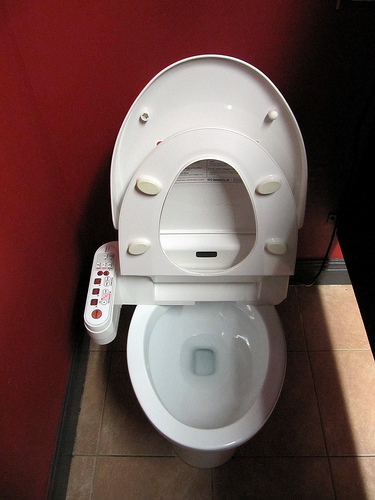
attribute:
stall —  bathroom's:
[1, 8, 366, 490]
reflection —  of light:
[230, 331, 254, 348]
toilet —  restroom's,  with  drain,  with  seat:
[83, 53, 310, 470]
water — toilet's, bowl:
[179, 336, 233, 383]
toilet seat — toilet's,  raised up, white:
[118, 125, 297, 278]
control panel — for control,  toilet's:
[83, 242, 117, 328]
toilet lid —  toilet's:
[109, 54, 309, 270]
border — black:
[47, 336, 89, 500]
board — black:
[336, 2, 374, 362]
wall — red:
[3, 6, 341, 498]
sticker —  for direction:
[174, 160, 245, 184]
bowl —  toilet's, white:
[157, 312, 260, 417]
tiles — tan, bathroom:
[67, 284, 374, 498]